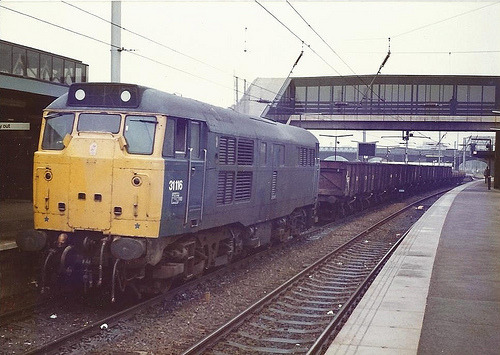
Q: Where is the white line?
A: On the platform.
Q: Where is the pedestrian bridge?
A: Over the train tracks.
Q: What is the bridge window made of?
A: Glass.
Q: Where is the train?
A: On the tracks.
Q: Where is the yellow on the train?
A: On the front.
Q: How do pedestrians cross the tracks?
A: By using the overpass.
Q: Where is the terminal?
A: Next to the tracks.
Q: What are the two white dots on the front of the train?
A: Lights.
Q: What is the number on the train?
A: 3116.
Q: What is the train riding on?
A: Tracks.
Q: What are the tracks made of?
A: Metal.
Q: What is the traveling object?
A: Train.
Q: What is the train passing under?
A: Pedway.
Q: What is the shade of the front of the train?
A: Yellow.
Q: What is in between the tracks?
A: Gravel.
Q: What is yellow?
A: The front of the train.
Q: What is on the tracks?
A: The train.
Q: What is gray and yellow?
A: The train.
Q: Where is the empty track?
A: Next to the train.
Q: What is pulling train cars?
A: The engine.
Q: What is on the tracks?
A: A train.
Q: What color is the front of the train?
A: Yellow.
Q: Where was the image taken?
A: A train station.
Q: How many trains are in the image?
A: One.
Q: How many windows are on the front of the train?
A: Three.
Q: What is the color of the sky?
A: White.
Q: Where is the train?
A: On a track.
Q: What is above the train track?
A: A walkway.